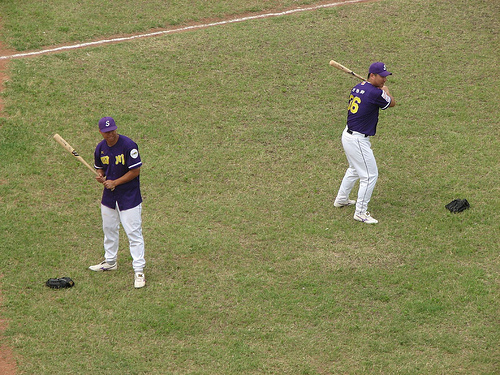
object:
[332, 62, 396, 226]
player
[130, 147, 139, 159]
badge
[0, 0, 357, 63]
line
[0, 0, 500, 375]
field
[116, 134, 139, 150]
shoulder